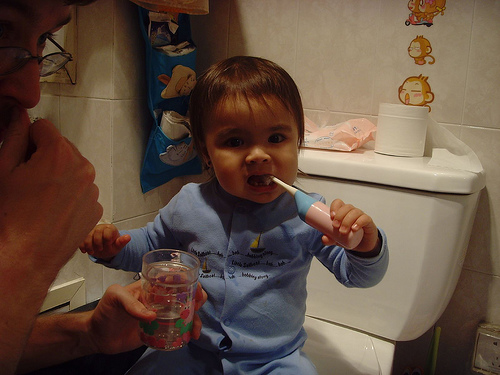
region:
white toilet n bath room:
[363, 163, 468, 337]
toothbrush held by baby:
[265, 181, 326, 229]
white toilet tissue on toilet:
[371, 95, 438, 182]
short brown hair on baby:
[205, 55, 272, 98]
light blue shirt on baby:
[186, 201, 297, 308]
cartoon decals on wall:
[394, 3, 441, 97]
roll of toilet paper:
[382, 105, 427, 154]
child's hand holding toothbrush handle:
[328, 196, 373, 253]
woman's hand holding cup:
[91, 255, 197, 343]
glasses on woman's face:
[9, 45, 71, 76]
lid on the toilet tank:
[333, 145, 447, 190]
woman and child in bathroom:
[3, 5, 328, 373]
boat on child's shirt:
[248, 230, 264, 253]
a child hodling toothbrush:
[209, 80, 353, 236]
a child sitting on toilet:
[189, 79, 297, 255]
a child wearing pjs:
[185, 59, 302, 331]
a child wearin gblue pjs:
[165, 88, 303, 374]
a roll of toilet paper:
[366, 90, 449, 177]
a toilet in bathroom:
[310, 78, 494, 313]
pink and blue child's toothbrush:
[259, 171, 363, 250]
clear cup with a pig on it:
[136, 248, 200, 352]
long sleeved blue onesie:
[86, 177, 391, 373]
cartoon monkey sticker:
[396, 73, 433, 111]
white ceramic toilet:
[296, 143, 486, 374]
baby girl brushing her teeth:
[76, 54, 389, 374]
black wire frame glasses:
[2, 35, 73, 77]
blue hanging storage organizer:
[138, 8, 205, 195]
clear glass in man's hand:
[130, 245, 208, 362]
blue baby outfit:
[85, 175, 392, 371]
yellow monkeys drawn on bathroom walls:
[387, 31, 454, 112]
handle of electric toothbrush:
[251, 174, 368, 256]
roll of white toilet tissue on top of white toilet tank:
[369, 96, 487, 188]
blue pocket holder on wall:
[133, 4, 209, 196]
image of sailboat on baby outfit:
[246, 230, 271, 254]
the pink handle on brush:
[307, 199, 357, 249]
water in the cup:
[146, 302, 187, 347]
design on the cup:
[154, 293, 196, 350]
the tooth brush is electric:
[266, 172, 362, 247]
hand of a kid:
[325, 203, 375, 256]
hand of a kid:
[79, 224, 132, 256]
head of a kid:
[193, 57, 306, 206]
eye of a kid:
[224, 134, 244, 147]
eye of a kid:
[270, 136, 286, 145]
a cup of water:
[142, 252, 194, 349]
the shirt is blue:
[117, 178, 386, 360]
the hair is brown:
[192, 54, 312, 158]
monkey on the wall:
[403, 34, 435, 66]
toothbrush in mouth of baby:
[258, 171, 364, 248]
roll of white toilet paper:
[373, 103, 484, 173]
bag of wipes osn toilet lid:
[298, 110, 374, 152]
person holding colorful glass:
[135, 247, 203, 354]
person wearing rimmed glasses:
[0, 32, 72, 80]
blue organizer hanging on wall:
[140, 29, 206, 194]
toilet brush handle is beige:
[428, 324, 441, 374]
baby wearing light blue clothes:
[85, 175, 390, 373]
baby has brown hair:
[192, 52, 306, 178]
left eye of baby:
[267, 133, 287, 146]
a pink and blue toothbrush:
[248, 162, 365, 258]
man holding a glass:
[8, 3, 220, 369]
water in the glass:
[129, 234, 208, 372]